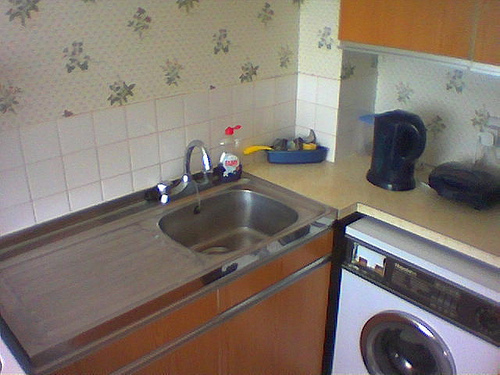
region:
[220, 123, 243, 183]
A bottle of dish soap on a sink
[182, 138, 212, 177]
A faucet over a sink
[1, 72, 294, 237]
White tile on a wall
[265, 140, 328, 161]
A dish with washing scrubbers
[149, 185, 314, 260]
A stainless steel sink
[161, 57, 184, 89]
Flower design on wallpaper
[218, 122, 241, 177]
plastic squeeze dish soap container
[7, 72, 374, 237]
white tiles on the wall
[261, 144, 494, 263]
light yellow countertop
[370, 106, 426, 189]
black electric tea kettle on the countertop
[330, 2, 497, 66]
cabinets above the countertop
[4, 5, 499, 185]
patterned wallpaper on the wall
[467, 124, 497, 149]
outlet on the wall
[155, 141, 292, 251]
sink and silver faucet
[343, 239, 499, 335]
control panel on dishwasher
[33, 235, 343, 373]
cabinets under the sink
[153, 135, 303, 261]
Silver faucet over a sink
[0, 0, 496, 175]
Wallpaper is on the wall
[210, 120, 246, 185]
Dish detergent in a bottle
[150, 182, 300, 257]
The sink is rectangular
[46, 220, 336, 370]
Wooden cabinets and drawers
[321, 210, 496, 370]
A white washing machine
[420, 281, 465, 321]
Buttons on the washing machine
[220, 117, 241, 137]
Red cap on a bottle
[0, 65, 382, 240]
White tiles on the wall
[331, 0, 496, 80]
Wooden and brown cabinets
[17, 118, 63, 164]
white tile on kitchen wall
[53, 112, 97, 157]
white tile on kitchen wall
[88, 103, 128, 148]
white tile on kitchen wall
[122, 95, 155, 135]
white tile on kitchen wall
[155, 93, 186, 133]
white tile on kitchen wall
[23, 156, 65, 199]
white tile on kitchen wall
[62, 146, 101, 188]
white tile on kitchen wall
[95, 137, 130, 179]
white tile on kitchen wall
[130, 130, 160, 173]
white tile on kitchen wall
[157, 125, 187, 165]
white tile on kitchen wall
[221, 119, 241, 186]
Dish liquid on the sink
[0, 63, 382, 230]
Tile backsplash behind the counter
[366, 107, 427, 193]
Blue pitcher on the counter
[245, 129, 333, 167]
Scrubbing utensils in a small blue tub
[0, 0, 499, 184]
Flowered wallpaper on the wall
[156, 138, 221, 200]
Faucet at the sink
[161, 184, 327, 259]
Silver sink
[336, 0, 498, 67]
Wooden cabinets above the counter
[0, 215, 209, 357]
Silver drying area to left of sink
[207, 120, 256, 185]
Dish soap is to the left of the faucet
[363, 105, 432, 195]
Black coffee maker is on the counter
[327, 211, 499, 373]
washing machine is to the right of the sink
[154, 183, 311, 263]
Sink is to the left of the yellow counter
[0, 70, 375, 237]
white tile above a kitchen sink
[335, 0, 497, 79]
brown cupboards on a wall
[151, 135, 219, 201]
silver sink faucet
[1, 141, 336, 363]
a silver kitchen sink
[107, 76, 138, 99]
A flower on the wall.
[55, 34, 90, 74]
A flower on the wall.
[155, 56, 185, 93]
A flower on the wall.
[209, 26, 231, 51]
A flower on the wall.